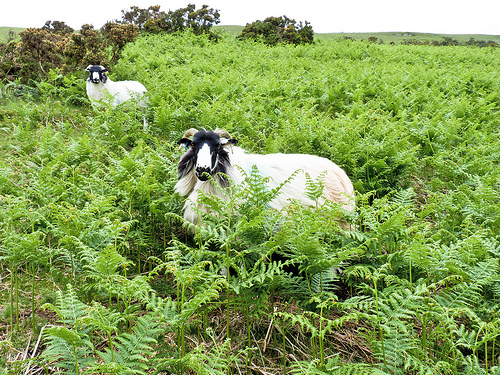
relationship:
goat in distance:
[82, 62, 151, 117] [3, 1, 496, 121]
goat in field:
[164, 113, 401, 243] [3, 45, 481, 365]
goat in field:
[82, 62, 151, 117] [3, 45, 481, 365]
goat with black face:
[82, 62, 151, 117] [85, 65, 103, 83]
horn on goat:
[181, 128, 198, 138] [170, 126, 355, 248]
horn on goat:
[82, 65, 93, 75] [81, 61, 149, 131]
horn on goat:
[101, 64, 113, 71] [80, 55, 151, 137]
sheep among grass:
[173, 127, 355, 232] [2, 26, 497, 370]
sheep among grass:
[82, 63, 151, 134] [2, 26, 497, 370]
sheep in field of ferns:
[173, 127, 355, 232] [2, 33, 498, 372]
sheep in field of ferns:
[73, 52, 203, 151] [2, 33, 498, 372]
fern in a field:
[7, 35, 497, 373] [3, 45, 481, 365]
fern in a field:
[440, 229, 487, 270] [2, 117, 431, 373]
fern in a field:
[439, 314, 476, 355] [2, 117, 431, 373]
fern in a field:
[227, 251, 304, 294] [2, 117, 431, 373]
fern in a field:
[50, 281, 90, 331] [2, 117, 431, 373]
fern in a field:
[197, 337, 237, 372] [2, 117, 431, 373]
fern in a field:
[407, 240, 467, 295] [3, 45, 481, 365]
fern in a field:
[409, 234, 466, 279] [3, 45, 481, 365]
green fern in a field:
[6, 38, 498, 370] [3, 45, 481, 365]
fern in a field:
[109, 161, 140, 191] [2, 0, 499, 374]